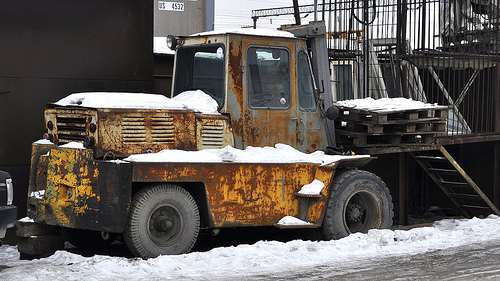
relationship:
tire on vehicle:
[122, 179, 207, 264] [28, 20, 394, 260]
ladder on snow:
[409, 143, 498, 216] [0, 211, 497, 279]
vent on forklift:
[119, 113, 174, 143] [30, 27, 498, 253]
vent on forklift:
[194, 120, 229, 150] [12, 9, 498, 267]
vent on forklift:
[194, 120, 229, 150] [30, 30, 457, 256]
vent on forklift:
[194, 120, 229, 150] [27, 20, 394, 257]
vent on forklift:
[119, 113, 174, 143] [30, 30, 457, 256]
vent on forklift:
[119, 113, 174, 143] [27, 20, 394, 257]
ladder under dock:
[409, 143, 498, 216] [358, 108, 498, 160]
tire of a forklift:
[122, 179, 207, 264] [11, 20, 393, 255]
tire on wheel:
[132, 191, 199, 249] [117, 182, 206, 257]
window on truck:
[244, 45, 290, 110] [34, 23, 400, 239]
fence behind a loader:
[314, 0, 499, 133] [17, 26, 498, 258]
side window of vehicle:
[237, 44, 302, 114] [55, 35, 392, 239]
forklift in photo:
[11, 20, 393, 255] [9, 9, 494, 276]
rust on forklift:
[135, 162, 209, 181] [11, 20, 393, 255]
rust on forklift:
[203, 164, 290, 224] [11, 20, 393, 255]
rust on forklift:
[227, 41, 242, 102] [11, 20, 393, 255]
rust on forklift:
[98, 110, 194, 149] [11, 20, 393, 255]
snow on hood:
[52, 82, 372, 180] [37, 72, 298, 172]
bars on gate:
[313, 0, 496, 134] [311, 2, 496, 140]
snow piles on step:
[112, 137, 371, 164] [294, 172, 329, 207]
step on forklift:
[294, 172, 329, 207] [11, 20, 393, 255]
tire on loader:
[320, 165, 407, 248] [18, 23, 441, 246]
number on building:
[156, 0, 183, 11] [2, 2, 153, 237]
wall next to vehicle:
[2, 0, 150, 231] [28, 20, 394, 260]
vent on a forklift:
[119, 113, 174, 143] [13, 20, 443, 263]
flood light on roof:
[164, 36, 180, 48] [166, 25, 315, 41]